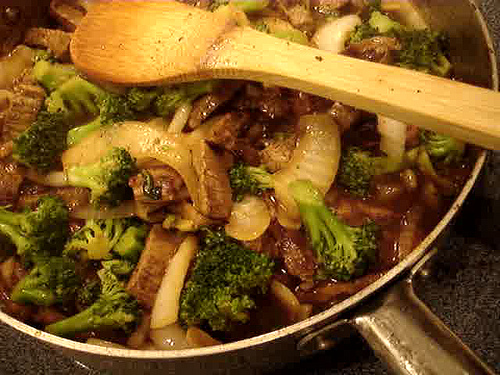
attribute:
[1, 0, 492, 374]
pot — metal, silver, steel, large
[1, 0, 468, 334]
vegetables — sauteed, cooked in juice, mixed, simmering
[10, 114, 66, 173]
broccoli — cooked, cut, dark, light green, green, chopped up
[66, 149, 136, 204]
broccoli — cooked, cut, dark, light green, green, chopped up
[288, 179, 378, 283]
broccoli — cooked, cut, dark, light green, green, chopped up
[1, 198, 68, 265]
broccoli — cooked, cut, dark, light green, green, chopped up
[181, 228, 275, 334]
broccoli — cooked, cut, dark, light green, green, chopped up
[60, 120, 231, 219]
onion — cooked, sliced, white, large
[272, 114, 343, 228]
onion — cooked, sliced, white, large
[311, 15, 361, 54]
onion — cooked, sliced, white, large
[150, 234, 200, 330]
onion — cooked, sliced, white, large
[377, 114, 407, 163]
onion — cooked, sliced, white, large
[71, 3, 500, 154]
spoon — to stir, wooden, made of wood, brown, for cooking, wet, light, for stirring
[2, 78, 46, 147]
meat — brown, cooked, sliced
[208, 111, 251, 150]
meat — brown, cooked, sliced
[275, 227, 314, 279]
meat — brown, cooked, sliced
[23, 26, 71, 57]
meat — brown, cooked, sliced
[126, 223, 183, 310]
meat — brown, cooked, sliced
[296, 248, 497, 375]
handle — silver, for holding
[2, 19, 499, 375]
countertop — speckled, gray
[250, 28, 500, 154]
handle — wooden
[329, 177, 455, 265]
gravy — brown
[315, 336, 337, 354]
screw — metal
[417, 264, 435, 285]
screw — metal